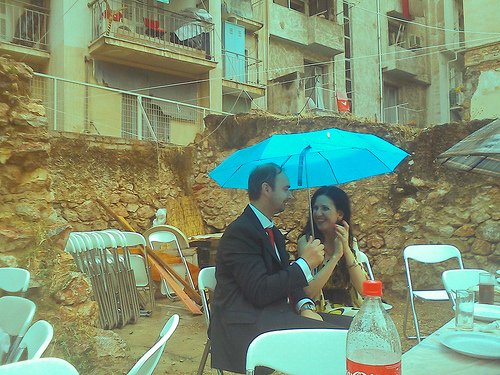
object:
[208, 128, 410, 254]
umbrella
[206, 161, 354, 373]
man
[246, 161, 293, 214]
head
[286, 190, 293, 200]
nose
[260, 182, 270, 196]
ear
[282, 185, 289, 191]
eye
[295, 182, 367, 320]
woman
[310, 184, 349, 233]
head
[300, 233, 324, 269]
hand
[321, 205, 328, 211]
eye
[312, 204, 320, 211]
eye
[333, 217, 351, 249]
hand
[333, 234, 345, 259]
hand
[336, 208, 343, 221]
ear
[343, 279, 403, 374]
bottle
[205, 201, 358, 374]
suit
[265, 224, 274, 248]
tie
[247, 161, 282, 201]
hair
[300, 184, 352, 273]
hair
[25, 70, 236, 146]
fence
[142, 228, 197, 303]
chairs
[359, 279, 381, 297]
cap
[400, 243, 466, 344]
folding chair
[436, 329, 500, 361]
plate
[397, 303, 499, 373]
table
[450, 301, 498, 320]
plate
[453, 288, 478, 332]
glass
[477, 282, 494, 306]
liquid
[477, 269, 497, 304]
glass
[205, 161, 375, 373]
couple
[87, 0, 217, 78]
balcony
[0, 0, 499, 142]
building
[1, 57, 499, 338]
wall